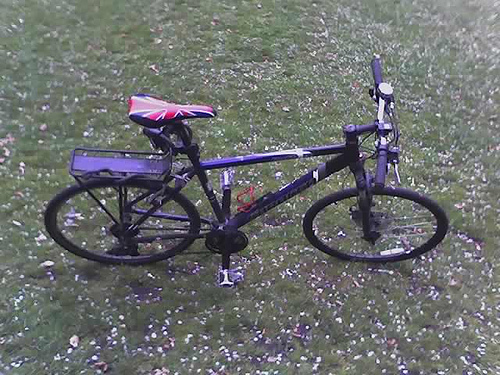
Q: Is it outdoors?
A: Yes, it is outdoors.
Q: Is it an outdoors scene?
A: Yes, it is outdoors.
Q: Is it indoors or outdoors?
A: It is outdoors.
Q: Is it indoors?
A: No, it is outdoors.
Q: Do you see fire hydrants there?
A: No, there are no fire hydrants.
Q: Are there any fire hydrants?
A: No, there are no fire hydrants.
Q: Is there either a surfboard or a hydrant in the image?
A: No, there are no fire hydrants or surfboards.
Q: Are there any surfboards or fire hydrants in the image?
A: No, there are no fire hydrants or surfboards.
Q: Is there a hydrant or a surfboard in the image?
A: No, there are no fire hydrants or surfboards.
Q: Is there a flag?
A: Yes, there is a flag.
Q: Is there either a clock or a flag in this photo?
A: Yes, there is a flag.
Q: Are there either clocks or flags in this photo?
A: Yes, there is a flag.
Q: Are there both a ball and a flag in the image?
A: No, there is a flag but no balls.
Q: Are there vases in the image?
A: No, there are no vases.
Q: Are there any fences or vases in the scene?
A: No, there are no vases or fences.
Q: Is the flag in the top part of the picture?
A: Yes, the flag is in the top of the image.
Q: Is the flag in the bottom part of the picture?
A: No, the flag is in the top of the image.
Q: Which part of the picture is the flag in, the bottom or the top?
A: The flag is in the top of the image.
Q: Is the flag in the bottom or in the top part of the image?
A: The flag is in the top of the image.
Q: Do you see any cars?
A: No, there are no cars.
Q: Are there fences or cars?
A: No, there are no cars or fences.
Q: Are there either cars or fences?
A: No, there are no cars or fences.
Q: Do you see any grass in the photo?
A: Yes, there is grass.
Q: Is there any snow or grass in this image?
A: Yes, there is grass.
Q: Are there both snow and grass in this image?
A: No, there is grass but no snow.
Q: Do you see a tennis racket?
A: No, there are no rackets.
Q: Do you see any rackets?
A: No, there are no rackets.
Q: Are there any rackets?
A: No, there are no rackets.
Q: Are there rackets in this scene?
A: No, there are no rackets.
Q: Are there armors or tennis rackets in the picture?
A: No, there are no tennis rackets or armors.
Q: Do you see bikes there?
A: Yes, there is a bike.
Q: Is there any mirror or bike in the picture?
A: Yes, there is a bike.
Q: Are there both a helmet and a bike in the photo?
A: No, there is a bike but no helmets.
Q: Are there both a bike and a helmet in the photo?
A: No, there is a bike but no helmets.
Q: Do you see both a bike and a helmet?
A: No, there is a bike but no helmets.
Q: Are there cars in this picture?
A: No, there are no cars.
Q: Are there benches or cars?
A: No, there are no cars or benches.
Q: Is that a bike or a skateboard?
A: That is a bike.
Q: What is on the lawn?
A: The bike is on the lawn.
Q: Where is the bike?
A: The bike is on the lawn.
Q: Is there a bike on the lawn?
A: Yes, there is a bike on the lawn.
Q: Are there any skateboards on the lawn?
A: No, there is a bike on the lawn.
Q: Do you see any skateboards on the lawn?
A: No, there is a bike on the lawn.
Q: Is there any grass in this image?
A: Yes, there is grass.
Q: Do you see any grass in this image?
A: Yes, there is grass.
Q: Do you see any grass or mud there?
A: Yes, there is grass.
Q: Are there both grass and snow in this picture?
A: No, there is grass but no snow.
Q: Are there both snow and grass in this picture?
A: No, there is grass but no snow.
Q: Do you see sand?
A: No, there is no sand.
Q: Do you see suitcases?
A: No, there are no suitcases.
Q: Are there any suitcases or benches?
A: No, there are no suitcases or benches.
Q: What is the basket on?
A: The basket is on the bike.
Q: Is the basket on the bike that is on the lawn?
A: Yes, the basket is on the bike.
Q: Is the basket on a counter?
A: No, the basket is on the bike.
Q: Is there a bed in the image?
A: No, there are no beds.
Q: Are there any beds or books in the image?
A: No, there are no beds or books.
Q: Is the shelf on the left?
A: Yes, the shelf is on the left of the image.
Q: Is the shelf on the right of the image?
A: No, the shelf is on the left of the image.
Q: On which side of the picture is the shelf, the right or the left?
A: The shelf is on the left of the image.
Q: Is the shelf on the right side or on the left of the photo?
A: The shelf is on the left of the image.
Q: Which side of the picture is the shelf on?
A: The shelf is on the left of the image.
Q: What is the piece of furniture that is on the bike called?
A: The piece of furniture is a shelf.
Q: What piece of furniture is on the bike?
A: The piece of furniture is a shelf.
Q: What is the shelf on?
A: The shelf is on the bike.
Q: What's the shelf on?
A: The shelf is on the bike.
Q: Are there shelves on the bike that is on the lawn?
A: Yes, there is a shelf on the bike.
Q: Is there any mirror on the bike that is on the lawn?
A: No, there is a shelf on the bike.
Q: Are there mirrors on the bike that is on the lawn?
A: No, there is a shelf on the bike.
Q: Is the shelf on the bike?
A: Yes, the shelf is on the bike.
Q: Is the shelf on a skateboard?
A: No, the shelf is on the bike.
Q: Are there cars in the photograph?
A: No, there are no cars.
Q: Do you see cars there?
A: No, there are no cars.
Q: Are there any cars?
A: No, there are no cars.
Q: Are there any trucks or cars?
A: No, there are no cars or trucks.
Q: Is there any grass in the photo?
A: Yes, there is grass.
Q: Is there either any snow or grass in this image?
A: Yes, there is grass.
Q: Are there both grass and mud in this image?
A: No, there is grass but no mud.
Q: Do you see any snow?
A: No, there is no snow.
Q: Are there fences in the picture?
A: No, there are no fences.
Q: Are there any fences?
A: No, there are no fences.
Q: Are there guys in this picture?
A: No, there are no guys.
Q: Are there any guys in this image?
A: No, there are no guys.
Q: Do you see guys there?
A: No, there are no guys.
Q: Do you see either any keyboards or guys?
A: No, there are no guys or keyboards.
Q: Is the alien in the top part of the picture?
A: Yes, the alien is in the top of the image.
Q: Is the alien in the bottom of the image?
A: No, the alien is in the top of the image.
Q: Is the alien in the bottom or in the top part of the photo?
A: The alien is in the top of the image.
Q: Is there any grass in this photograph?
A: Yes, there is grass.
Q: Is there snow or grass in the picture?
A: Yes, there is grass.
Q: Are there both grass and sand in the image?
A: No, there is grass but no sand.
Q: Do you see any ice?
A: No, there is no ice.